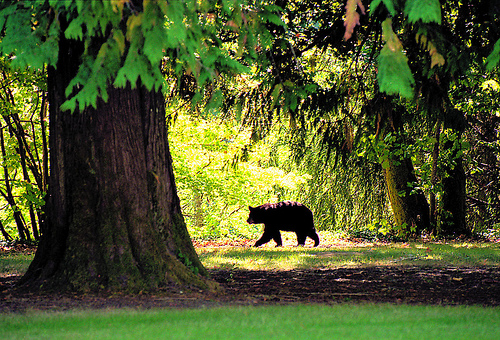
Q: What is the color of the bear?
A: Is brown.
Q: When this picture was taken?
A: During the day.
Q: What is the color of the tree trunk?
A: Is brown and green.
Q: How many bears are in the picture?
A: One.